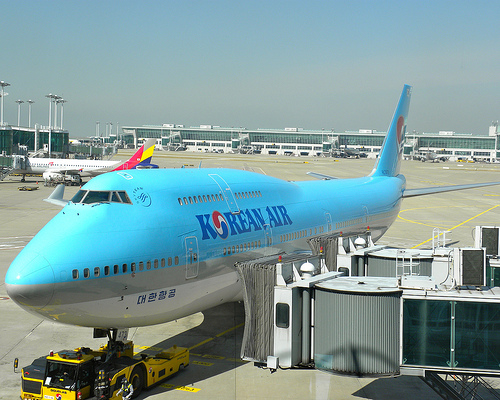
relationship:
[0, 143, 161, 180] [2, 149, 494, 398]
jet on tarmac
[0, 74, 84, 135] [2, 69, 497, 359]
light poles in airport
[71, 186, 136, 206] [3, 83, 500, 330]
windows in plane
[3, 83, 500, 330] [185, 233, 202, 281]
plane has door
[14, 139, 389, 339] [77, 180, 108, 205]
plane has window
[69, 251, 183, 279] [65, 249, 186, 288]
windows in row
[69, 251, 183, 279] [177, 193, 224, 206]
windows in levels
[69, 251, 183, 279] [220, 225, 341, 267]
windows in row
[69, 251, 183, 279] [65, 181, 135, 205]
windows in row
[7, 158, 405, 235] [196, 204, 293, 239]
top has writing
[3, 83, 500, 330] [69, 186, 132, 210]
plane has windows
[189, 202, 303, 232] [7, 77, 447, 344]
letters on plane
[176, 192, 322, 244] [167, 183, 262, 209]
levels of windows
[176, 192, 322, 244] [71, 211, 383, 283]
levels of windows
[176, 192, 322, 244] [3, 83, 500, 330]
levels on plane